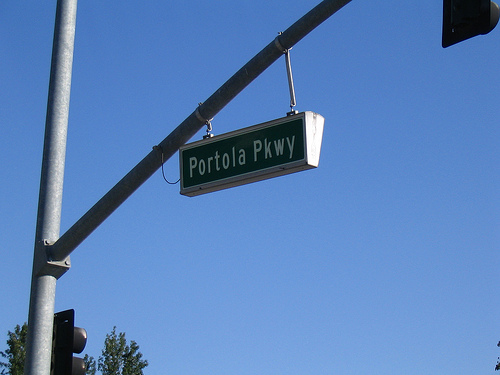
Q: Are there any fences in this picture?
A: No, there are no fences.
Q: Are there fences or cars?
A: No, there are no fences or cars.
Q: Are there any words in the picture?
A: Yes, there are words.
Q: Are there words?
A: Yes, there are words.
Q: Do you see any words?
A: Yes, there are words.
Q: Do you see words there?
A: Yes, there are words.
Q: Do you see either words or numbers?
A: Yes, there are words.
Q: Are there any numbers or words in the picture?
A: Yes, there are words.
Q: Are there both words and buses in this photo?
A: No, there are words but no buses.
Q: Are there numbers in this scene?
A: No, there are no numbers.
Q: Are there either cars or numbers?
A: No, there are no numbers or cars.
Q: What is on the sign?
A: The words are on the sign.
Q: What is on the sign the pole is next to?
A: The words are on the sign.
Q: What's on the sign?
A: The words are on the sign.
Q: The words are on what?
A: The words are on the sign.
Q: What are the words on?
A: The words are on the sign.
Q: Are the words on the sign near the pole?
A: Yes, the words are on the sign.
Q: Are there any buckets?
A: No, there are no buckets.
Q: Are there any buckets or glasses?
A: No, there are no buckets or glasses.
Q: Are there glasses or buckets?
A: No, there are no buckets or glasses.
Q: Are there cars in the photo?
A: No, there are no cars.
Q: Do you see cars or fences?
A: No, there are no cars or fences.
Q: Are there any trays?
A: No, there are no trays.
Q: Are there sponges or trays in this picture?
A: No, there are no trays or sponges.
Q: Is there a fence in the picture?
A: No, there are no fences.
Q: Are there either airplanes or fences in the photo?
A: No, there are no fences or airplanes.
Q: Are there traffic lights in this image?
A: Yes, there is a traffic light.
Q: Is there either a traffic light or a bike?
A: Yes, there is a traffic light.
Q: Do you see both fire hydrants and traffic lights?
A: No, there is a traffic light but no fire hydrants.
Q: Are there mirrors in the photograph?
A: No, there are no mirrors.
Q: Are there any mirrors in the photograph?
A: No, there are no mirrors.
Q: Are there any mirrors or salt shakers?
A: No, there are no mirrors or salt shakers.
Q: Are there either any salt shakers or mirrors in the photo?
A: No, there are no mirrors or salt shakers.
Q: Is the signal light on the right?
A: Yes, the signal light is on the right of the image.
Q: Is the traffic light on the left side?
A: No, the traffic light is on the right of the image.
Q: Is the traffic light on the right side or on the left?
A: The traffic light is on the right of the image.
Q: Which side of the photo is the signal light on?
A: The signal light is on the right of the image.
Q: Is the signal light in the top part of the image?
A: Yes, the signal light is in the top of the image.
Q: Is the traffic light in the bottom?
A: No, the traffic light is in the top of the image.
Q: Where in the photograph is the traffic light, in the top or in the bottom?
A: The traffic light is in the top of the image.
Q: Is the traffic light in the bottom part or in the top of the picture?
A: The traffic light is in the top of the image.